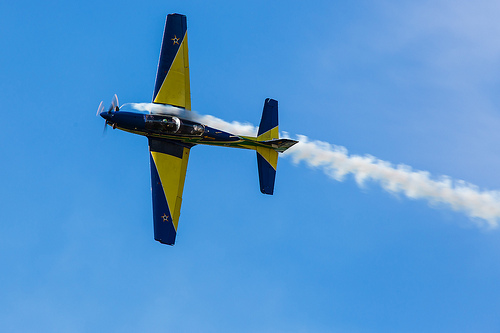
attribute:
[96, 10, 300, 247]
jet — flying, sideways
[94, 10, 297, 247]
plane — colorful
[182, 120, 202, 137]
seat — empty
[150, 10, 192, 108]
right wing — blue, yellow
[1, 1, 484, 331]
sky — bright blue, big, blue, clear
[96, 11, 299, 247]
airplane — beautiful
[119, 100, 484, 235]
smoke — gray, white